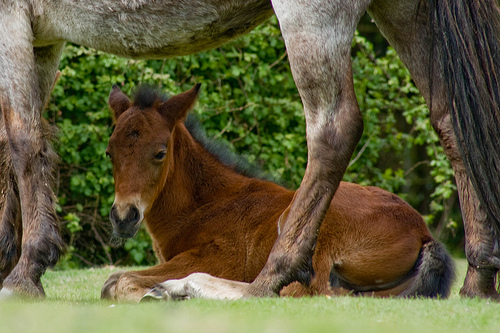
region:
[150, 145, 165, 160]
eye of the horse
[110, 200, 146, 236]
nose of the horse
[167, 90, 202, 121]
ear of the horse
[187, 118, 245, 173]
mane on the horse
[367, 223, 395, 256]
the horse is brown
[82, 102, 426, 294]
the colt is laying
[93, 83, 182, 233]
head of the horse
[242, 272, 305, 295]
hoof of the horse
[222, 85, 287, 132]
leaves on the bushes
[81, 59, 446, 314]
foal sitting under mother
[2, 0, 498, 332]
brown foal with dappled mother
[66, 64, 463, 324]
foal laying in the grass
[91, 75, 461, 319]
brown foal with black mane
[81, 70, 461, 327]
brown foal has brown ears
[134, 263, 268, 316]
foal has white hind leg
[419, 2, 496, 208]
horse's long black tail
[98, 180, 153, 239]
foal has white ring on muzzle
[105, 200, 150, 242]
foal has black nose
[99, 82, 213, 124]
foals ears are standing up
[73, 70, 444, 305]
baby horse under mama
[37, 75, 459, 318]
baby horse under mama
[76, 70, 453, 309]
baby horse under mama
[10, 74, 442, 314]
baby horse under mama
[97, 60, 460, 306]
baby horse under mama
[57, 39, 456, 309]
baby horse under mama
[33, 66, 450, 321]
baby horse under mama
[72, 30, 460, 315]
baby horse under mama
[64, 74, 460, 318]
baby horse under mama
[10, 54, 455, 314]
baby horse under mama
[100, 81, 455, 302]
a baby horse laying in the grass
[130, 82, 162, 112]
the colts black mane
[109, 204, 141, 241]
the colts black nose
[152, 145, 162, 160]
the dark eyes of the baby horse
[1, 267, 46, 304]
the horses brown hooves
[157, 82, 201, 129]
the colts brown ear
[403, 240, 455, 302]
the colts black tail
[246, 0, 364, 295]
the horses brown leg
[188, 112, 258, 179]
the black hair on the colts neck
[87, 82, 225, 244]
the head of a horse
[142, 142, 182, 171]
the eye of a horse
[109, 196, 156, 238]
the nose of a horse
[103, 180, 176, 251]
the mouth of a horse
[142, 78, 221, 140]
the ear of a horse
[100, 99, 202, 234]
the face of a horse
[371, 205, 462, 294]
the tail of a horse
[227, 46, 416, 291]
the back leg of a horse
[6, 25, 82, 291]
the front leg of a horse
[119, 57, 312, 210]
the main of a horse